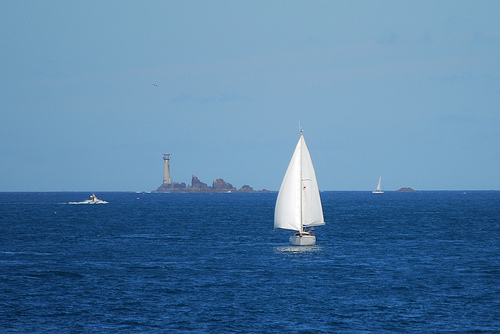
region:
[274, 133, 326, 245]
A boat with a large white sail.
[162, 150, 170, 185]
A large grey lighthouse.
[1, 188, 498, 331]
A bright blue sea.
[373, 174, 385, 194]
White sailboat in the distance.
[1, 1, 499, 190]
A blue sky.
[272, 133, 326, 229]
The largest white sail.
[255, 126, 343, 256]
this is a boat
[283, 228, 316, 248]
the boat is white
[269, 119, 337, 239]
sail on the boat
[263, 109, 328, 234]
the sail is white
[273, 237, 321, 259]
reflection of the boat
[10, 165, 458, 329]
a large body of water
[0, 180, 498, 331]
the water is blue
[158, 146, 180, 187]
tower in the background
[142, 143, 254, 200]
land mass in background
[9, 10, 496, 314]
a bright and clear day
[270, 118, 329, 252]
white sail boat in blue water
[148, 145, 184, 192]
grey stone lighthouse on land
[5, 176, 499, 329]
crystal blue sea water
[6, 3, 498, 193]
clear blue cloudless sky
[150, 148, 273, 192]
land mass with buildings and lighthouse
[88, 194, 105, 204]
person on jet ski in blue water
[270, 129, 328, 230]
white sails unfurled on sail boat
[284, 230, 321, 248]
white wooden sail boat in blue water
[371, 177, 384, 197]
white sail boat seen in the distance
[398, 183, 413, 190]
distant lan mass in blue water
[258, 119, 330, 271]
boat with white sail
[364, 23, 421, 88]
white clouds in blue sky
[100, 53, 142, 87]
white clouds in blue sky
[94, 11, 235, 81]
white clouds in blue sky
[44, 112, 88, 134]
white clouds in blue sky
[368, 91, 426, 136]
white clouds in blue sky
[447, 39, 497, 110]
white clouds in blue sky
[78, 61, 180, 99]
white clouds in blue sky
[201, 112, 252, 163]
white clouds in blue sky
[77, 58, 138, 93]
white clouds in blue sky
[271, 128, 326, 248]
Sailboat on the water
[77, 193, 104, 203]
Boat on the water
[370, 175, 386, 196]
Sailboat on the water in the distance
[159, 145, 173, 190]
Lighthouse in the distance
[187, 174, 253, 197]
Buildings in the distance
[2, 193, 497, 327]
Blue ocean water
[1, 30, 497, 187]
Cloudless blue sky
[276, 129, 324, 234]
Two sails on the sailboat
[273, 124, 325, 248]
Boat sailing in the blue water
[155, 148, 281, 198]
island in the distance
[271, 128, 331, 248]
Sailboat has 2 white sails on it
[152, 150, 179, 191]
Lighthouse is seen in the distance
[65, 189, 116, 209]
Jet ski out on the water left of the sail boat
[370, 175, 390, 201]
White sail boat seen in the distance